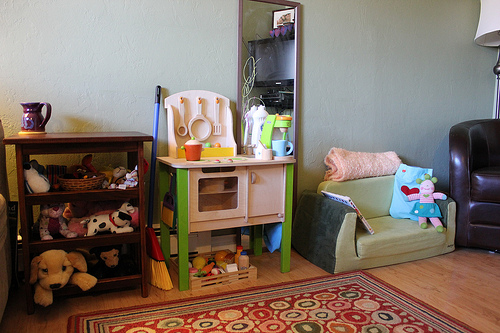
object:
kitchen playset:
[155, 89, 298, 290]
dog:
[26, 248, 97, 306]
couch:
[292, 174, 456, 275]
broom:
[147, 84, 174, 290]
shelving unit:
[4, 130, 154, 313]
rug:
[66, 268, 483, 331]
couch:
[448, 115, 499, 257]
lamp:
[471, 0, 499, 46]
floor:
[1, 245, 499, 331]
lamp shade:
[471, 0, 499, 48]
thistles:
[143, 253, 173, 291]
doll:
[404, 172, 448, 232]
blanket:
[323, 145, 400, 182]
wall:
[1, 1, 499, 238]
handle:
[145, 83, 162, 229]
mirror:
[235, 1, 304, 255]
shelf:
[30, 274, 140, 299]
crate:
[173, 247, 256, 292]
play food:
[197, 260, 217, 276]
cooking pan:
[188, 96, 211, 143]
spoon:
[176, 96, 187, 140]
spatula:
[211, 94, 222, 137]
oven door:
[188, 167, 247, 226]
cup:
[20, 100, 53, 134]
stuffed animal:
[81, 201, 137, 236]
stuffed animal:
[32, 198, 76, 240]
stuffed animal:
[87, 241, 135, 278]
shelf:
[27, 231, 140, 252]